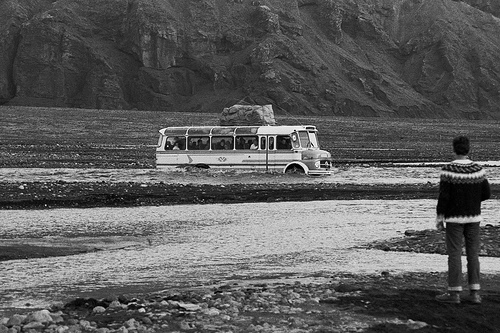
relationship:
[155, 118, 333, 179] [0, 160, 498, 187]
bus driving through water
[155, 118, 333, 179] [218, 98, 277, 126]
bus carrying cargo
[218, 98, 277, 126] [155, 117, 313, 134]
cargo on bus' roof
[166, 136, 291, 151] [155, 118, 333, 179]
people are in bus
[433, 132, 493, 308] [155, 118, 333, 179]
man watching bus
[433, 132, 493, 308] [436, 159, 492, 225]
man wearing a sweater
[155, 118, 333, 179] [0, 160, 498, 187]
bus in water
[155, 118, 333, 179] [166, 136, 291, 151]
bus has people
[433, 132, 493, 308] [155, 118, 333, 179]
man looking at bus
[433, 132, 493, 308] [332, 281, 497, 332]
man standing in dirt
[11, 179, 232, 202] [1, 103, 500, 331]
rocks are on ground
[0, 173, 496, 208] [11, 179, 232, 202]
dirt near rocks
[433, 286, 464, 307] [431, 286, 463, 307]
shoe on foot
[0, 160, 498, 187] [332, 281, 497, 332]
water near dirt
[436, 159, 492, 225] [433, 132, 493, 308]
sweater on man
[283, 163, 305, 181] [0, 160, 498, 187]
tire in water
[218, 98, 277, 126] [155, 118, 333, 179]
cargo on top of bus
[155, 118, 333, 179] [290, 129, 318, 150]
bus has a windshield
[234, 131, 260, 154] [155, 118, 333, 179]
window on side of bus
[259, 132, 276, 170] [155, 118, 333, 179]
door on side of bus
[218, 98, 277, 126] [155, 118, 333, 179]
cargo on bus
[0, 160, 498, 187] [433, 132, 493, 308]
water in front of man